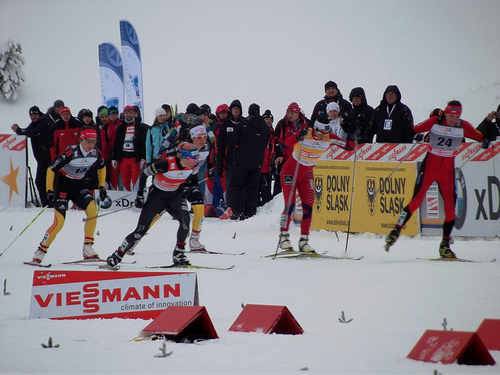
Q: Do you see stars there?
A: Yes, there is a star.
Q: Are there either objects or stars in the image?
A: Yes, there is a star.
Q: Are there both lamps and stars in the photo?
A: No, there is a star but no lamps.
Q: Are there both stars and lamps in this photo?
A: No, there is a star but no lamps.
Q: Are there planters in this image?
A: No, there are no planters.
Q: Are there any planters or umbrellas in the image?
A: No, there are no planters or umbrellas.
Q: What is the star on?
A: The star is on the sign.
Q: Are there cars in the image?
A: No, there are no cars.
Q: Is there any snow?
A: Yes, there is snow.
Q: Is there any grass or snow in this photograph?
A: Yes, there is snow.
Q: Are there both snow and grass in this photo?
A: No, there is snow but no grass.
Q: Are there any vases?
A: No, there are no vases.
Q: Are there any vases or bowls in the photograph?
A: No, there are no vases or bowls.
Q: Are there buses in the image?
A: No, there are no buses.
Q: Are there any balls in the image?
A: No, there are no balls.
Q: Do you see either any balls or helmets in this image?
A: No, there are no balls or helmets.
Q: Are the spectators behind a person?
A: Yes, the spectators are behind a person.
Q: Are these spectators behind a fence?
A: No, the spectators are behind a person.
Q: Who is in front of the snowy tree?
A: The spectators are in front of the tree.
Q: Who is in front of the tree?
A: The spectators are in front of the tree.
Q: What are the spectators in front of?
A: The spectators are in front of the tree.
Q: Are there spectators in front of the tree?
A: Yes, there are spectators in front of the tree.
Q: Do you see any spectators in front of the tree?
A: Yes, there are spectators in front of the tree.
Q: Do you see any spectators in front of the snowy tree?
A: Yes, there are spectators in front of the tree.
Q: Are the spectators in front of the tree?
A: Yes, the spectators are in front of the tree.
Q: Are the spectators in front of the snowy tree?
A: Yes, the spectators are in front of the tree.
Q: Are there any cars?
A: No, there are no cars.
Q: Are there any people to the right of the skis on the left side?
A: Yes, there is a person to the right of the skis.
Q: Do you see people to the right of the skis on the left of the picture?
A: Yes, there is a person to the right of the skis.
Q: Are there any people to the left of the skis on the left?
A: No, the person is to the right of the skis.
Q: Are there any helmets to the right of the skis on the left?
A: No, there is a person to the right of the skis.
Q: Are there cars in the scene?
A: No, there are no cars.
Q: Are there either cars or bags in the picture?
A: No, there are no cars or bags.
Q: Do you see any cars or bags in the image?
A: No, there are no cars or bags.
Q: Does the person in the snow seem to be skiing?
A: Yes, the person is skiing.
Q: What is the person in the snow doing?
A: The person is skiing.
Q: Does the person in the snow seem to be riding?
A: No, the person is skiing.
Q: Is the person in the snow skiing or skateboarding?
A: The person is skiing.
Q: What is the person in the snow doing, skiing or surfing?
A: The person is skiing.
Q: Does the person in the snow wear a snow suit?
A: Yes, the person wears a snow suit.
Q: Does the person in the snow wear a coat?
A: No, the person wears a snow suit.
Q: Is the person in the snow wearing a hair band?
A: Yes, the person is wearing a hair band.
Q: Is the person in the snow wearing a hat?
A: No, the person is wearing a hair band.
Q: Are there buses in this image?
A: No, there are no buses.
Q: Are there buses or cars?
A: No, there are no buses or cars.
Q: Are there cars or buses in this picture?
A: No, there are no buses or cars.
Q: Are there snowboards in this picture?
A: No, there are no snowboards.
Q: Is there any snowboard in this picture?
A: No, there are no snowboards.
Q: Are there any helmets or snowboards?
A: No, there are no snowboards or helmets.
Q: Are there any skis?
A: Yes, there are skis.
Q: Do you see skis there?
A: Yes, there are skis.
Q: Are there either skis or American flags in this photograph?
A: Yes, there are skis.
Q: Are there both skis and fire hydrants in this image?
A: No, there are skis but no fire hydrants.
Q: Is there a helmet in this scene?
A: No, there are no helmets.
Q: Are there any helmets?
A: No, there are no helmets.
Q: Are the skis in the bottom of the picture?
A: Yes, the skis are in the bottom of the image.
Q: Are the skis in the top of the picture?
A: No, the skis are in the bottom of the image.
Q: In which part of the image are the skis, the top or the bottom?
A: The skis are in the bottom of the image.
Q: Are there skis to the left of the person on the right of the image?
A: Yes, there are skis to the left of the person.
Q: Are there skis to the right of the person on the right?
A: No, the skis are to the left of the person.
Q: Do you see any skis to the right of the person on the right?
A: No, the skis are to the left of the person.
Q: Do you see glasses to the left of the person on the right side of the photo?
A: No, there are skis to the left of the person.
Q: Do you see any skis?
A: Yes, there are skis.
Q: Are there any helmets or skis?
A: Yes, there are skis.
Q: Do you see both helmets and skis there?
A: No, there are skis but no helmets.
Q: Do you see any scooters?
A: No, there are no scooters.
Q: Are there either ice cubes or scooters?
A: No, there are no scooters or ice cubes.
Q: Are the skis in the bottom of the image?
A: Yes, the skis are in the bottom of the image.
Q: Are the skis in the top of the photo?
A: No, the skis are in the bottom of the image.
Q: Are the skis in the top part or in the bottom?
A: The skis are in the bottom of the image.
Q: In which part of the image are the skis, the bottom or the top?
A: The skis are in the bottom of the image.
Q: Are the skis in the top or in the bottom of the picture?
A: The skis are in the bottom of the image.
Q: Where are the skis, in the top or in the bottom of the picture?
A: The skis are in the bottom of the image.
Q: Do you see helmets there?
A: No, there are no helmets.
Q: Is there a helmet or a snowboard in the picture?
A: No, there are no helmets or snowboards.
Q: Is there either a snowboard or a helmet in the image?
A: No, there are no helmets or snowboards.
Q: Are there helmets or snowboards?
A: No, there are no helmets or snowboards.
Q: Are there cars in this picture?
A: No, there are no cars.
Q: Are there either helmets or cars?
A: No, there are no cars or helmets.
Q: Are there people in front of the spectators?
A: Yes, there is a person in front of the spectators.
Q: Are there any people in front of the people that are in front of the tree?
A: Yes, there is a person in front of the spectators.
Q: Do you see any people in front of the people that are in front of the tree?
A: Yes, there is a person in front of the spectators.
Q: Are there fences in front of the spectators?
A: No, there is a person in front of the spectators.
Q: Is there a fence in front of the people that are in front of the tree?
A: No, there is a person in front of the spectators.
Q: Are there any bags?
A: No, there are no bags.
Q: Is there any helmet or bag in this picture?
A: No, there are no bags or helmets.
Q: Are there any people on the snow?
A: Yes, there is a person on the snow.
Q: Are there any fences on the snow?
A: No, there is a person on the snow.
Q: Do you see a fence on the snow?
A: No, there is a person on the snow.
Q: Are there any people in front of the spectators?
A: Yes, there is a person in front of the spectators.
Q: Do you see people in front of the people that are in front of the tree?
A: Yes, there is a person in front of the spectators.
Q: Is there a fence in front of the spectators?
A: No, there is a person in front of the spectators.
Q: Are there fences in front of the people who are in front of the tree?
A: No, there is a person in front of the spectators.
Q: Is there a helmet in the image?
A: No, there are no helmets.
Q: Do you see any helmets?
A: No, there are no helmets.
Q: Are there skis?
A: Yes, there are skis.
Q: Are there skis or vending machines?
A: Yes, there are skis.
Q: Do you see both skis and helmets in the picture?
A: No, there are skis but no helmets.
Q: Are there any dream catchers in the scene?
A: No, there are no dream catchers.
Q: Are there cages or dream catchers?
A: No, there are no dream catchers or cages.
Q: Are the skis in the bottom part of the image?
A: Yes, the skis are in the bottom of the image.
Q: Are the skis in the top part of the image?
A: No, the skis are in the bottom of the image.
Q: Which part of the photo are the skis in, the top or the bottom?
A: The skis are in the bottom of the image.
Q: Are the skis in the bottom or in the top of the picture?
A: The skis are in the bottom of the image.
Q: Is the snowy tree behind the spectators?
A: Yes, the tree is behind the spectators.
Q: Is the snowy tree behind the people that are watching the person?
A: Yes, the tree is behind the spectators.